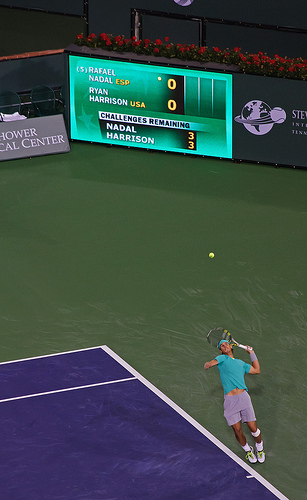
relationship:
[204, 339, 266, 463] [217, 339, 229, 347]
man wearing headband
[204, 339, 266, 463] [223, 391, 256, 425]
man wearing shorts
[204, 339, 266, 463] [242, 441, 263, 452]
man wearing socks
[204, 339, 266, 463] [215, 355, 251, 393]
man wearing t-shirt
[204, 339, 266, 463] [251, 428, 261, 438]
man wearing leg wrap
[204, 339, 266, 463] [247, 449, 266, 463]
man wearing shoes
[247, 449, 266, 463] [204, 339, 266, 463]
shoes are of man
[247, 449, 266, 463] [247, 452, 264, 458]
shoes have laces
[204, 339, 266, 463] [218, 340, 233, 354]
man has head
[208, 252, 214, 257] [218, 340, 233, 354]
tennis ball above head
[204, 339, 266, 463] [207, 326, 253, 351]
man holding racket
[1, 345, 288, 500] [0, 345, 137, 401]
tennis court has lines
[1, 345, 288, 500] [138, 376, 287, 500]
tennis court has line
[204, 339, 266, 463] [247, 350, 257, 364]
man has band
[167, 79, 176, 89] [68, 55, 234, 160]
number on board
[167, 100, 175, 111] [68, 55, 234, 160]
number on board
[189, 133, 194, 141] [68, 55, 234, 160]
number on board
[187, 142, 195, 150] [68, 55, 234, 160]
number on board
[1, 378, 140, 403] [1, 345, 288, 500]
line on tennis court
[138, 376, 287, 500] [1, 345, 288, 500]
line on tennis court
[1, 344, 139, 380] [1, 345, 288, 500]
edge on tennis court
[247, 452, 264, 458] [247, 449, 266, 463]
laces on shoes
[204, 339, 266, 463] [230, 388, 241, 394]
man has belly button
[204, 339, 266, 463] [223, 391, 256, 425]
man has shorts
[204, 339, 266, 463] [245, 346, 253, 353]
man has hand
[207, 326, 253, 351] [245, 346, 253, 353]
racket in hand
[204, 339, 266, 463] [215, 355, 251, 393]
man has t-shirt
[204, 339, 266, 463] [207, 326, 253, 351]
man swinging racket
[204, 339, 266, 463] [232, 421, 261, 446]
man has legs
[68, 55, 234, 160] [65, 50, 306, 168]
board on wall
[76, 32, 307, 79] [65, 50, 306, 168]
flowers are on wall